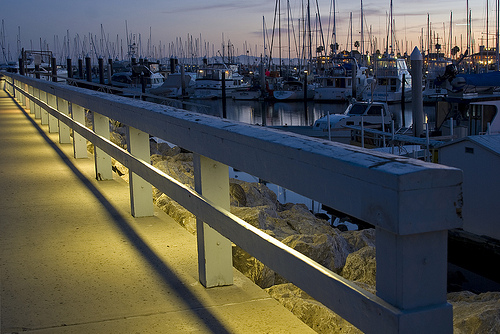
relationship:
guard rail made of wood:
[4, 65, 465, 333] [243, 129, 340, 195]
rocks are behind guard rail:
[229, 173, 357, 297] [4, 65, 465, 333]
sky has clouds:
[5, 4, 496, 53] [255, 7, 385, 46]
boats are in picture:
[52, 48, 493, 224] [3, 4, 498, 333]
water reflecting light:
[190, 96, 338, 127] [234, 104, 268, 125]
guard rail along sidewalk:
[4, 65, 465, 333] [3, 92, 313, 333]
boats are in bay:
[52, 48, 493, 224] [36, 50, 499, 220]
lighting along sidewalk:
[16, 86, 136, 183] [3, 92, 313, 333]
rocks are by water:
[229, 173, 357, 297] [190, 96, 338, 127]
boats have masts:
[52, 48, 493, 224] [27, 7, 491, 64]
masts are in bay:
[27, 7, 491, 64] [36, 50, 499, 220]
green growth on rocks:
[274, 281, 344, 332] [229, 173, 357, 297]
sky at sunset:
[5, 4, 496, 53] [302, 11, 498, 51]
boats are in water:
[52, 48, 493, 224] [190, 96, 338, 127]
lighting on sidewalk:
[16, 86, 136, 183] [3, 92, 313, 333]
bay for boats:
[36, 50, 499, 220] [52, 48, 493, 224]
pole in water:
[208, 69, 239, 129] [190, 96, 338, 127]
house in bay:
[418, 122, 499, 277] [36, 50, 499, 220]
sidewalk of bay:
[3, 92, 313, 333] [36, 50, 499, 220]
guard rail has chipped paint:
[4, 65, 465, 333] [366, 146, 400, 175]